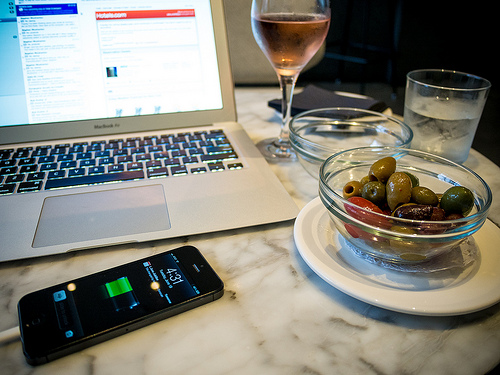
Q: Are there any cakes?
A: No, there are no cakes.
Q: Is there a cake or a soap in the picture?
A: No, there are no cakes or soaps.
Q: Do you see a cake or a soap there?
A: No, there are no cakes or soaps.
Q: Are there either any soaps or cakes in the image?
A: No, there are no cakes or soaps.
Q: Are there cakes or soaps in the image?
A: No, there are no cakes or soaps.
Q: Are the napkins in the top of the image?
A: Yes, the napkins are in the top of the image.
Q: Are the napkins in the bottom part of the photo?
A: No, the napkins are in the top of the image.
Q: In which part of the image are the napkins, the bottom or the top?
A: The napkins are in the top of the image.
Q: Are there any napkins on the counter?
A: Yes, there are napkins on the counter.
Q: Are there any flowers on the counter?
A: No, there are napkins on the counter.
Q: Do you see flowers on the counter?
A: No, there are napkins on the counter.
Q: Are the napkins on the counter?
A: Yes, the napkins are on the counter.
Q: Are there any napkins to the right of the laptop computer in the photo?
A: Yes, there are napkins to the right of the laptop computer.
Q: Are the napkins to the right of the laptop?
A: Yes, the napkins are to the right of the laptop.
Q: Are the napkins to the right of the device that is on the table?
A: Yes, the napkins are to the right of the laptop.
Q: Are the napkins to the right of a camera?
A: No, the napkins are to the right of the laptop.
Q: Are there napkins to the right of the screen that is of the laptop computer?
A: Yes, there are napkins to the right of the screen.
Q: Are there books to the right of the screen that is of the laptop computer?
A: No, there are napkins to the right of the screen.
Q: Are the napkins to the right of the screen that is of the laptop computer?
A: Yes, the napkins are to the right of the screen.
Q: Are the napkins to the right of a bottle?
A: No, the napkins are to the right of the screen.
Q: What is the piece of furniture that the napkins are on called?
A: The piece of furniture is a table.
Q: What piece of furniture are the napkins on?
A: The napkins are on the table.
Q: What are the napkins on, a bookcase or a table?
A: The napkins are on a table.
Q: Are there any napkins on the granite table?
A: Yes, there are napkins on the table.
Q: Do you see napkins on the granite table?
A: Yes, there are napkins on the table.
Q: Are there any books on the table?
A: No, there are napkins on the table.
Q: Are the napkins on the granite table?
A: Yes, the napkins are on the table.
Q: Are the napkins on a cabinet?
A: No, the napkins are on the table.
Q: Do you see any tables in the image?
A: Yes, there is a table.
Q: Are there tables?
A: Yes, there is a table.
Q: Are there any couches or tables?
A: Yes, there is a table.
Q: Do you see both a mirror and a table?
A: No, there is a table but no mirrors.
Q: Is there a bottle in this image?
A: No, there are no bottles.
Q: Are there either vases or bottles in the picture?
A: No, there are no bottles or vases.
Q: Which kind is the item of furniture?
A: The piece of furniture is a table.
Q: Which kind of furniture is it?
A: The piece of furniture is a table.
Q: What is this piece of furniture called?
A: This is a table.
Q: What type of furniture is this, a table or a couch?
A: This is a table.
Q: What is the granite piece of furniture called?
A: The piece of furniture is a table.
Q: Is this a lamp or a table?
A: This is a table.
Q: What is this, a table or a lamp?
A: This is a table.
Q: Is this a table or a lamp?
A: This is a table.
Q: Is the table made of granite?
A: Yes, the table is made of granite.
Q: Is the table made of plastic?
A: No, the table is made of granite.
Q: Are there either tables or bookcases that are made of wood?
A: No, there is a table but it is made of granite.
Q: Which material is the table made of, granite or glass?
A: The table is made of granite.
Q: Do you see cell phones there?
A: Yes, there is a cell phone.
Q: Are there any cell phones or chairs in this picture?
A: Yes, there is a cell phone.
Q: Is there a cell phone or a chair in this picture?
A: Yes, there is a cell phone.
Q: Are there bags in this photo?
A: No, there are no bags.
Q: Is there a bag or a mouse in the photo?
A: No, there are no bags or computer mice.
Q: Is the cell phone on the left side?
A: Yes, the cell phone is on the left of the image.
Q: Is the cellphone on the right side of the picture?
A: No, the cellphone is on the left of the image.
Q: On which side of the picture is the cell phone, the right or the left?
A: The cell phone is on the left of the image.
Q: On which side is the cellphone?
A: The cellphone is on the left of the image.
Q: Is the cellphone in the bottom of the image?
A: Yes, the cellphone is in the bottom of the image.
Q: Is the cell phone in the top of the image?
A: No, the cell phone is in the bottom of the image.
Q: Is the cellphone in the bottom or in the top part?
A: The cellphone is in the bottom of the image.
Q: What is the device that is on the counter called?
A: The device is a cell phone.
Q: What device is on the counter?
A: The device is a cell phone.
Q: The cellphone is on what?
A: The cellphone is on the counter.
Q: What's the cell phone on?
A: The cellphone is on the counter.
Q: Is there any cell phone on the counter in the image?
A: Yes, there is a cell phone on the counter.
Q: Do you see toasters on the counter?
A: No, there is a cell phone on the counter.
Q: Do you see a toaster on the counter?
A: No, there is a cell phone on the counter.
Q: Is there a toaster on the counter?
A: No, there is a cell phone on the counter.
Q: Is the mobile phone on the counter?
A: Yes, the mobile phone is on the counter.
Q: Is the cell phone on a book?
A: No, the cell phone is on the counter.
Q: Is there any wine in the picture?
A: Yes, there is wine.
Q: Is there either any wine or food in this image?
A: Yes, there is wine.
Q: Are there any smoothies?
A: No, there are no smoothies.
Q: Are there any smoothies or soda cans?
A: No, there are no smoothies or soda cans.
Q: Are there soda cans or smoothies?
A: No, there are no smoothies or soda cans.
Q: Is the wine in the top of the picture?
A: Yes, the wine is in the top of the image.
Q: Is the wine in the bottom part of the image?
A: No, the wine is in the top of the image.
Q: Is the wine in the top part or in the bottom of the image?
A: The wine is in the top of the image.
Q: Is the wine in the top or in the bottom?
A: The wine is in the top of the image.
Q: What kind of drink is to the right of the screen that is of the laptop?
A: The drink is wine.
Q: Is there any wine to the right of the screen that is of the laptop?
A: Yes, there is wine to the right of the screen.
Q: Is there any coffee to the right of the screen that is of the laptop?
A: No, there is wine to the right of the screen.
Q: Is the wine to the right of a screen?
A: Yes, the wine is to the right of a screen.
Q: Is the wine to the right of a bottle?
A: No, the wine is to the right of a screen.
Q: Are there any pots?
A: No, there are no pots.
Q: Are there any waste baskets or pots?
A: No, there are no pots or waste baskets.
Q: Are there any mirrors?
A: No, there are no mirrors.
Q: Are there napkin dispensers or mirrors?
A: No, there are no mirrors or napkin dispensers.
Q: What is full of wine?
A: The glass is full of wine.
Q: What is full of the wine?
A: The glass is full of wine.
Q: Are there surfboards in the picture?
A: No, there are no surfboards.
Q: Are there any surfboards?
A: No, there are no surfboards.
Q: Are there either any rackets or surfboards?
A: No, there are no surfboards or rackets.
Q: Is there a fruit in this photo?
A: Yes, there is a fruit.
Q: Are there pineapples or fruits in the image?
A: Yes, there is a fruit.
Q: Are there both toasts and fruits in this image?
A: No, there is a fruit but no toasts.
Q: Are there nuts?
A: No, there are no nuts.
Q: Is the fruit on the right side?
A: Yes, the fruit is on the right of the image.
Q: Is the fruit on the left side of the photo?
A: No, the fruit is on the right of the image.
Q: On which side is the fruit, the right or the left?
A: The fruit is on the right of the image.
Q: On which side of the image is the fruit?
A: The fruit is on the right of the image.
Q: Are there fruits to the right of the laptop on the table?
A: Yes, there is a fruit to the right of the laptop.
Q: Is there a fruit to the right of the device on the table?
A: Yes, there is a fruit to the right of the laptop.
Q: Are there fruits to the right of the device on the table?
A: Yes, there is a fruit to the right of the laptop.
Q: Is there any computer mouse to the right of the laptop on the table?
A: No, there is a fruit to the right of the laptop.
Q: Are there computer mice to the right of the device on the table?
A: No, there is a fruit to the right of the laptop.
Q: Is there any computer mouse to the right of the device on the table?
A: No, there is a fruit to the right of the laptop.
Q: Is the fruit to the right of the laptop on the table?
A: Yes, the fruit is to the right of the laptop.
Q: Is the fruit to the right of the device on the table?
A: Yes, the fruit is to the right of the laptop.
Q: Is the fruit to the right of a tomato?
A: No, the fruit is to the right of the laptop.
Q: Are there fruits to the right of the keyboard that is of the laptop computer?
A: Yes, there is a fruit to the right of the keyboard.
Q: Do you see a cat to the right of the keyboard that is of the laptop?
A: No, there is a fruit to the right of the keyboard.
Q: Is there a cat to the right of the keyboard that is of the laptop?
A: No, there is a fruit to the right of the keyboard.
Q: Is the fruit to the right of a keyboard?
A: Yes, the fruit is to the right of a keyboard.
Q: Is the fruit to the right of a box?
A: No, the fruit is to the right of a keyboard.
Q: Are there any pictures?
A: No, there are no pictures.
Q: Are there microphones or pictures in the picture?
A: No, there are no pictures or microphones.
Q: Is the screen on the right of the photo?
A: No, the screen is on the left of the image.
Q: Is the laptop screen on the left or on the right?
A: The screen is on the left of the image.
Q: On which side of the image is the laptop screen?
A: The screen is on the left of the image.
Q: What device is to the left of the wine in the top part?
A: The device is a screen.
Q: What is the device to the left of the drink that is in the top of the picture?
A: The device is a screen.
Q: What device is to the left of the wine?
A: The device is a screen.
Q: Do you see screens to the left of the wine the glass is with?
A: Yes, there is a screen to the left of the wine.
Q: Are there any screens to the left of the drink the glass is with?
A: Yes, there is a screen to the left of the wine.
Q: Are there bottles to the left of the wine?
A: No, there is a screen to the left of the wine.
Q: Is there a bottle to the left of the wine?
A: No, there is a screen to the left of the wine.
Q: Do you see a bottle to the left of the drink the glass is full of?
A: No, there is a screen to the left of the wine.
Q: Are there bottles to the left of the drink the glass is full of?
A: No, there is a screen to the left of the wine.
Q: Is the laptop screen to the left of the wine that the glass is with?
A: Yes, the screen is to the left of the wine.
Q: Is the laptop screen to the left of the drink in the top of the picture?
A: Yes, the screen is to the left of the wine.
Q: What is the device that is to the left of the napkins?
A: The device is a screen.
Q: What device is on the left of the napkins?
A: The device is a screen.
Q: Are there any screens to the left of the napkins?
A: Yes, there is a screen to the left of the napkins.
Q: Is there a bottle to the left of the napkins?
A: No, there is a screen to the left of the napkins.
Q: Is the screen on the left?
A: Yes, the screen is on the left of the image.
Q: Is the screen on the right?
A: No, the screen is on the left of the image.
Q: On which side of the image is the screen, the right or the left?
A: The screen is on the left of the image.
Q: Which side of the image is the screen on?
A: The screen is on the left of the image.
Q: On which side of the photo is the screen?
A: The screen is on the left of the image.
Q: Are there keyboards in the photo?
A: Yes, there is a keyboard.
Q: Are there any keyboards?
A: Yes, there is a keyboard.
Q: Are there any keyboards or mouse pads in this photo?
A: Yes, there is a keyboard.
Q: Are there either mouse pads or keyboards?
A: Yes, there is a keyboard.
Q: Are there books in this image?
A: No, there are no books.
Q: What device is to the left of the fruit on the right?
A: The device is a keyboard.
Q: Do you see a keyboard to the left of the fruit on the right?
A: Yes, there is a keyboard to the left of the fruit.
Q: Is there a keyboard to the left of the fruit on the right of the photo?
A: Yes, there is a keyboard to the left of the fruit.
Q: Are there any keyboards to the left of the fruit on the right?
A: Yes, there is a keyboard to the left of the fruit.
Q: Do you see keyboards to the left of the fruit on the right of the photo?
A: Yes, there is a keyboard to the left of the fruit.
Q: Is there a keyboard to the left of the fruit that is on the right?
A: Yes, there is a keyboard to the left of the fruit.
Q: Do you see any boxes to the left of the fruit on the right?
A: No, there is a keyboard to the left of the fruit.